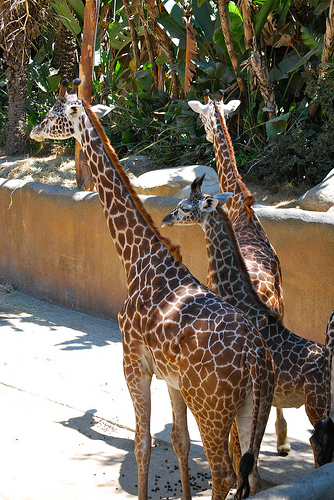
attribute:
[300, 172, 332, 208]
rock — large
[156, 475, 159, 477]
stone — black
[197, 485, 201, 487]
stone — black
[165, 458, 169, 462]
stone — black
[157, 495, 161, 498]
stone — black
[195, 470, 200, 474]
stone — black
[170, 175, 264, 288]
giraffe — younger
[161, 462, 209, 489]
rocks — black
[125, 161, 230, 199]
rock — large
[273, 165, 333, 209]
rock — Big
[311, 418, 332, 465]
hair — black, long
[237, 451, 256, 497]
hair — black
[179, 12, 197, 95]
leaf — dead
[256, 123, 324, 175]
bush — small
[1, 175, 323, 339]
wall — cement